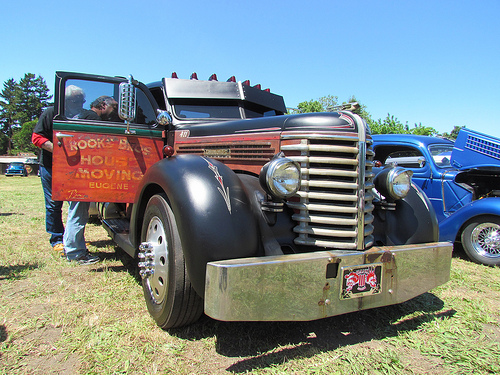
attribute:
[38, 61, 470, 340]
vehicle — large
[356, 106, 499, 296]
truck — blue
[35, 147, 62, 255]
man — standing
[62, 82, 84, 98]
hair — white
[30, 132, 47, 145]
shirt sleeve — red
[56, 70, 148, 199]
door — open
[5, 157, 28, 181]
car — blue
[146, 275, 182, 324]
tire — giant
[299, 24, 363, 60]
sky — blue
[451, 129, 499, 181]
hood up — open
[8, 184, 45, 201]
field — grassy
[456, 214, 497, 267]
wheel — metal